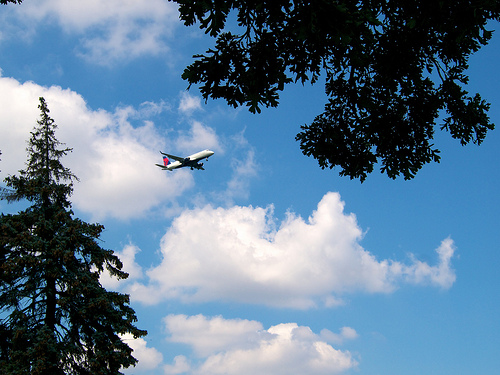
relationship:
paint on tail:
[162, 155, 167, 165] [160, 155, 170, 170]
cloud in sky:
[201, 169, 476, 327] [1, 0, 499, 372]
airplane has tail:
[154, 149, 218, 171] [151, 159, 175, 176]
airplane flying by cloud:
[154, 149, 218, 171] [115, 198, 460, 305]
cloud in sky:
[124, 190, 460, 308] [1, 0, 499, 372]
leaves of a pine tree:
[193, 52, 492, 184] [0, 95, 148, 374]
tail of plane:
[160, 151, 171, 169] [153, 147, 214, 173]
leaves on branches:
[6, 325, 65, 373] [24, 284, 86, 374]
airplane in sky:
[117, 70, 257, 234] [23, 17, 473, 331]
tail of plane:
[154, 153, 171, 169] [157, 148, 212, 171]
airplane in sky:
[154, 149, 218, 171] [1, 0, 499, 372]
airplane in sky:
[154, 149, 218, 171] [120, 174, 498, 374]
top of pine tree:
[23, 91, 59, 142] [0, 95, 148, 374]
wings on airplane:
[159, 149, 208, 178] [153, 144, 215, 177]